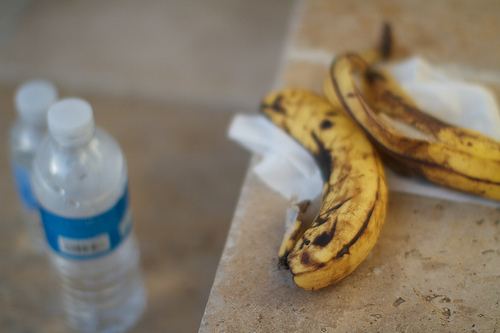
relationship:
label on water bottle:
[35, 178, 137, 264] [28, 97, 146, 333]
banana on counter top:
[263, 87, 385, 290] [195, 0, 500, 333]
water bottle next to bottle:
[45, 105, 160, 329] [0, 79, 62, 254]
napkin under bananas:
[220, 47, 498, 217] [251, 48, 498, 298]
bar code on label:
[58, 234, 112, 256] [33, 183, 131, 264]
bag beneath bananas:
[226, 49, 499, 214] [251, 48, 498, 298]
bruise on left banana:
[299, 124, 344, 155] [236, 71, 411, 259]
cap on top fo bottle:
[13, 77, 60, 122] [28, 97, 150, 331]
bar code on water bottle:
[51, 236, 99, 251] [28, 97, 146, 333]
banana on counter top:
[259, 83, 389, 291] [195, 0, 500, 333]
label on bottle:
[33, 183, 131, 264] [28, 97, 150, 331]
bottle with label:
[7, 79, 54, 253] [10, 164, 39, 205]